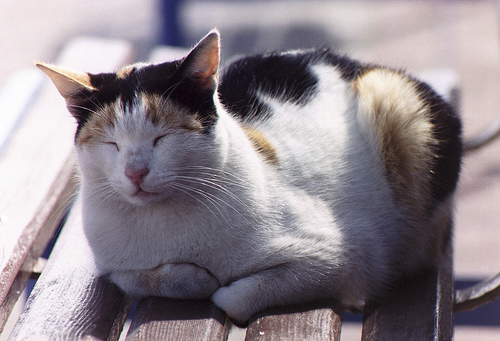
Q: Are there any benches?
A: Yes, there is a bench.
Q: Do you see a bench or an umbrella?
A: Yes, there is a bench.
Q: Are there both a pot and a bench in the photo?
A: No, there is a bench but no pots.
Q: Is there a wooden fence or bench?
A: Yes, there is a wood bench.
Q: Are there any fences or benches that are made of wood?
A: Yes, the bench is made of wood.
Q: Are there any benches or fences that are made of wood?
A: Yes, the bench is made of wood.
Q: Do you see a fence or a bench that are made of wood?
A: Yes, the bench is made of wood.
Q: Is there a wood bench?
A: Yes, there is a bench that is made of wood.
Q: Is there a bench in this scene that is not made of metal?
A: Yes, there is a bench that is made of wood.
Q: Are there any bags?
A: No, there are no bags.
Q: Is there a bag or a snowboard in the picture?
A: No, there are no bags or snowboards.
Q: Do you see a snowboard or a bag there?
A: No, there are no bags or snowboards.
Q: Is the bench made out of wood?
A: Yes, the bench is made of wood.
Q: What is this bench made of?
A: The bench is made of wood.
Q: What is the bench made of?
A: The bench is made of wood.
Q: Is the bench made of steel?
A: No, the bench is made of wood.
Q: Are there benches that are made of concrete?
A: No, there is a bench but it is made of wood.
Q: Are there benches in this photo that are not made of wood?
A: No, there is a bench but it is made of wood.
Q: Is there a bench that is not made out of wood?
A: No, there is a bench but it is made of wood.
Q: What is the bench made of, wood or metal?
A: The bench is made of wood.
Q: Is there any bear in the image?
A: No, there are no bears.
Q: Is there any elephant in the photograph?
A: No, there are no elephants.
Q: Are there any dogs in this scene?
A: No, there are no dogs.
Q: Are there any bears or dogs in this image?
A: No, there are no dogs or bears.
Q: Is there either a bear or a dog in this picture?
A: No, there are no dogs or bears.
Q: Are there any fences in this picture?
A: No, there are no fences.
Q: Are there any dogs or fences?
A: No, there are no fences or dogs.